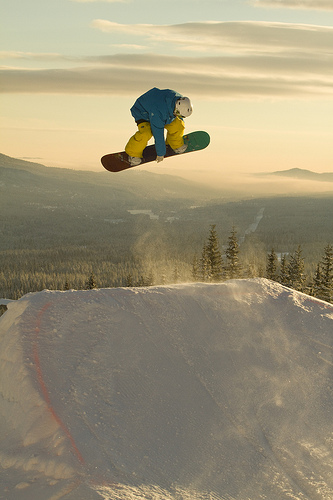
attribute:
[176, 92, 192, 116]
helmet — white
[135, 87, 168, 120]
coat — blue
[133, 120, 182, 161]
pants — yellow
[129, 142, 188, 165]
shoes — white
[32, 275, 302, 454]
snow — white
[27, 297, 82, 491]
line — orange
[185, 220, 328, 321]
trees — tall, green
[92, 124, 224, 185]
snowboard — getting air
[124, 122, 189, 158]
pants — yellow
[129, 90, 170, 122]
jacket — blue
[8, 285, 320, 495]
snow ramp — for snowboarders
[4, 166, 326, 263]
mountains — in distance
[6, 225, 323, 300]
valley — wooded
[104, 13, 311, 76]
clouds — white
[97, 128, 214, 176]
snowboard — red and green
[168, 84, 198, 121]
helmet — white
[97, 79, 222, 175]
boy — on air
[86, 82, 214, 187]
boy — skating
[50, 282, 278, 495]
path — hilly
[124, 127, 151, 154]
trousers — yellow in color